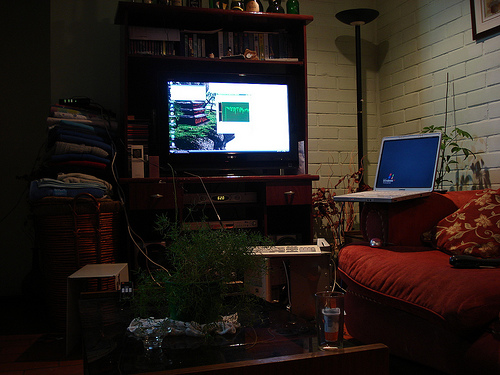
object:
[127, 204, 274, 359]
plant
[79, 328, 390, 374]
table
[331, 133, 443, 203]
laptop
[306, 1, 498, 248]
brick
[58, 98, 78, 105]
box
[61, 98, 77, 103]
lights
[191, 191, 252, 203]
box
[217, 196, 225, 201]
time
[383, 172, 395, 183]
logo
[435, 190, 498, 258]
pillow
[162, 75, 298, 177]
tv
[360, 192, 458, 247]
arm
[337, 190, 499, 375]
sofa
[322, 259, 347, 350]
glass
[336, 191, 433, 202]
keyboard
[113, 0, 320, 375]
entertainment center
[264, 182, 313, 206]
drawer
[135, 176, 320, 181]
shelf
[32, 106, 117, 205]
clothes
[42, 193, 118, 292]
basket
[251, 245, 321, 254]
keyboard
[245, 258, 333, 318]
box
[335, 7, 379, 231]
lamp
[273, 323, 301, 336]
dish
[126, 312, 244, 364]
pot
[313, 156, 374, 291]
plant